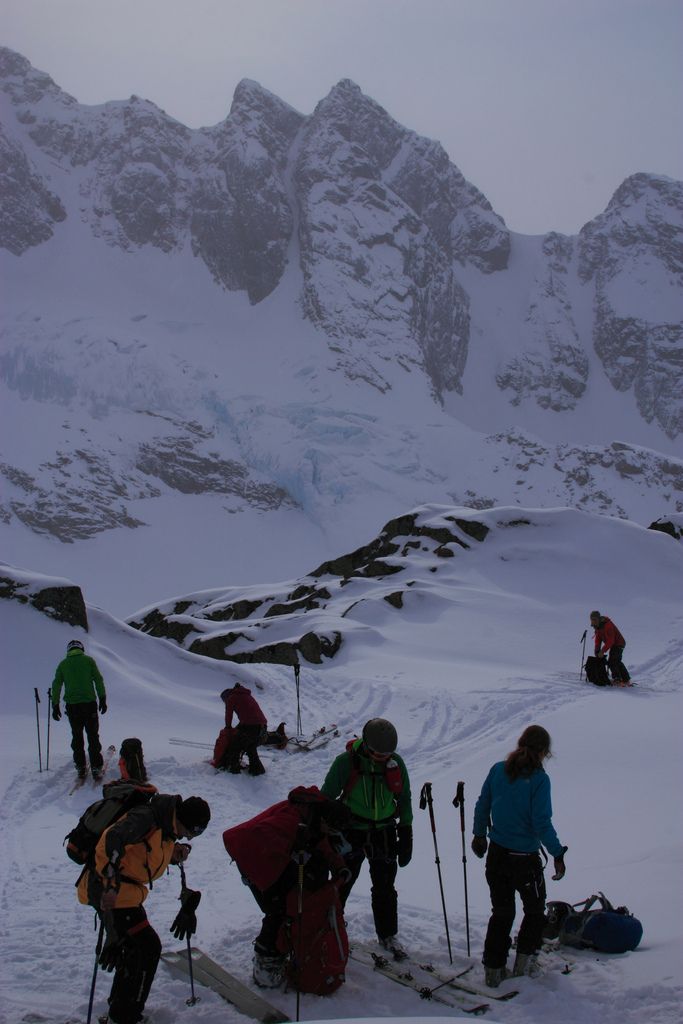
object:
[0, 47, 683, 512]
snow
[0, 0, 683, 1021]
mountain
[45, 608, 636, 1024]
people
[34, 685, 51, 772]
poles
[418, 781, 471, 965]
poles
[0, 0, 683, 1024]
snow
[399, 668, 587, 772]
snow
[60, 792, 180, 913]
jacket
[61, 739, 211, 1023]
man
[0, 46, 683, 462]
mountains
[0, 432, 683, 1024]
ground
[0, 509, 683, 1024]
snow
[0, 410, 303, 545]
snow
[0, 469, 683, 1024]
snow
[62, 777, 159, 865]
backpack